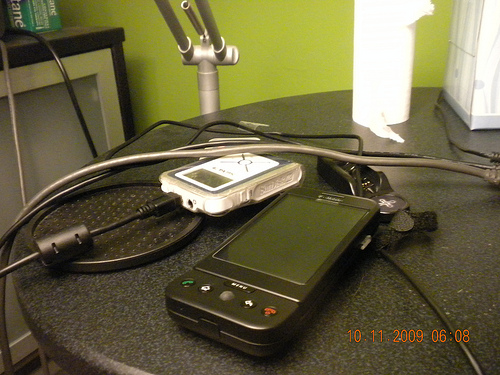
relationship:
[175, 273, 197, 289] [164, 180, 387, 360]
button on phone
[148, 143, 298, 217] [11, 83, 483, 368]
device on table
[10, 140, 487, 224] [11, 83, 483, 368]
cord on table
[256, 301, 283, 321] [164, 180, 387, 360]
button on phone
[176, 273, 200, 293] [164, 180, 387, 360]
button on phone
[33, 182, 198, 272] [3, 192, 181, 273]
charger under cord